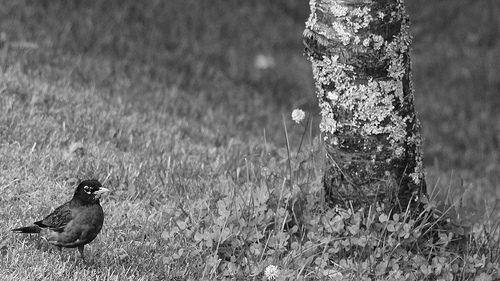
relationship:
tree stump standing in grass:
[302, 0, 440, 237] [1, 1, 484, 278]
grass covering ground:
[1, 1, 484, 278] [2, 2, 498, 280]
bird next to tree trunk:
[10, 180, 109, 266] [302, 0, 431, 218]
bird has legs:
[10, 180, 109, 266] [55, 245, 90, 266]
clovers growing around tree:
[158, 170, 498, 279] [300, 0, 447, 232]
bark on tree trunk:
[300, 2, 431, 222] [302, 0, 431, 218]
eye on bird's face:
[84, 182, 93, 194] [69, 179, 111, 202]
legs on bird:
[54, 246, 99, 268] [11, 174, 112, 268]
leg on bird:
[53, 247, 67, 264] [11, 174, 112, 268]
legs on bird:
[76, 246, 86, 258] [11, 174, 112, 268]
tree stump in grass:
[302, 0, 440, 237] [1, 1, 484, 278]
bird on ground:
[10, 180, 109, 266] [2, 2, 498, 280]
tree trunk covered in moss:
[336, 25, 438, 200] [346, 80, 402, 134]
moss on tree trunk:
[348, 84, 397, 147] [299, 14, 432, 211]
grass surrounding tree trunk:
[1, 1, 484, 278] [303, 16, 446, 198]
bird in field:
[26, 170, 104, 240] [44, 96, 256, 264]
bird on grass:
[10, 180, 109, 266] [45, 97, 300, 246]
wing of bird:
[38, 209, 75, 226] [30, 171, 124, 258]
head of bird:
[72, 176, 107, 202] [31, 175, 138, 249]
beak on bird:
[94, 186, 109, 195] [21, 173, 129, 261]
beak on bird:
[94, 182, 109, 195] [20, 177, 112, 265]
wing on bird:
[33, 210, 75, 227] [26, 168, 124, 254]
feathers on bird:
[14, 207, 45, 228] [18, 167, 113, 258]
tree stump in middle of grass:
[302, 0, 440, 237] [1, 1, 484, 278]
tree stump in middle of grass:
[302, 0, 418, 184] [1, 1, 484, 278]